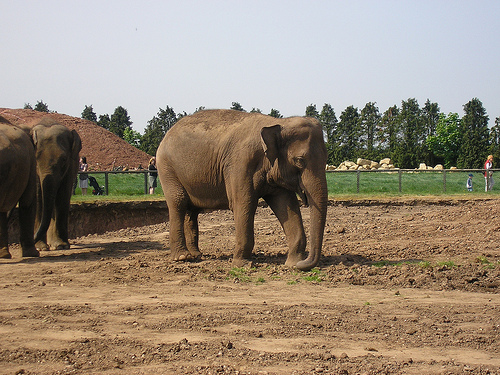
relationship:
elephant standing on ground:
[154, 109, 326, 268] [0, 170, 499, 374]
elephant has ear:
[154, 109, 326, 268] [260, 122, 281, 165]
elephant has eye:
[154, 109, 326, 268] [295, 155, 306, 167]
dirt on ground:
[0, 196, 499, 374] [0, 170, 499, 374]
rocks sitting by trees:
[323, 156, 459, 173] [15, 97, 498, 172]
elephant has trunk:
[154, 109, 326, 268] [298, 177, 328, 270]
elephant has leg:
[154, 109, 326, 268] [232, 204, 255, 265]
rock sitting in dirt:
[224, 340, 235, 349] [0, 196, 499, 374]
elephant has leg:
[154, 109, 326, 268] [158, 156, 194, 260]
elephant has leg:
[154, 109, 326, 268] [183, 207, 203, 258]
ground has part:
[0, 170, 499, 374] [406, 207, 483, 237]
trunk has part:
[298, 177, 328, 270] [296, 258, 316, 270]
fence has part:
[71, 169, 498, 194] [399, 169, 446, 195]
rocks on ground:
[323, 156, 459, 173] [0, 170, 499, 374]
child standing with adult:
[465, 173, 475, 192] [481, 153, 493, 196]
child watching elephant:
[465, 173, 475, 192] [154, 109, 326, 268]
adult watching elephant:
[481, 153, 493, 196] [154, 109, 326, 268]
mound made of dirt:
[0, 200, 169, 242] [0, 196, 499, 374]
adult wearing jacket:
[481, 153, 493, 196] [482, 161, 494, 178]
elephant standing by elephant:
[26, 120, 83, 252] [1, 116, 42, 256]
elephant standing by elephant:
[1, 116, 42, 256] [26, 120, 83, 252]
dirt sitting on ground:
[0, 196, 499, 374] [0, 170, 499, 374]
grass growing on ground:
[72, 170, 498, 193] [0, 170, 499, 374]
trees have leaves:
[15, 97, 498, 172] [461, 103, 488, 167]